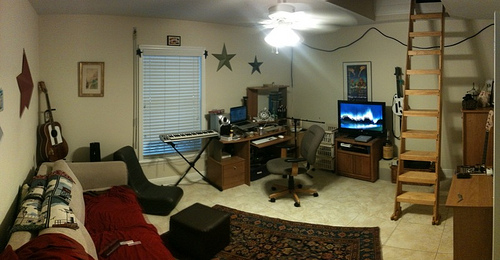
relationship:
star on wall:
[208, 41, 241, 73] [1, 2, 495, 241]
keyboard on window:
[158, 121, 244, 160] [125, 21, 229, 183]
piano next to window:
[156, 125, 224, 195] [131, 43, 208, 160]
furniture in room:
[7, 146, 197, 256] [7, 12, 499, 259]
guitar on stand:
[31, 75, 72, 159] [39, 105, 61, 161]